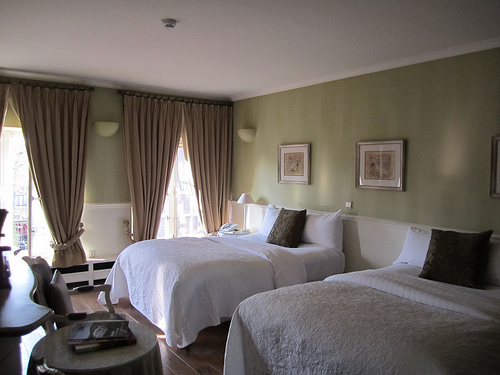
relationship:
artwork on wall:
[354, 137, 407, 194] [230, 46, 500, 239]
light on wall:
[93, 118, 121, 138] [0, 74, 237, 295]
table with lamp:
[205, 229, 252, 240] [238, 191, 255, 232]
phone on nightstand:
[219, 221, 238, 233] [215, 228, 255, 238]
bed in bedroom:
[221, 226, 499, 374] [2, 1, 498, 374]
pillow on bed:
[266, 205, 307, 248] [99, 233, 348, 351]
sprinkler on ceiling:
[162, 18, 178, 29] [2, 2, 500, 103]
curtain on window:
[1, 83, 94, 269] [3, 126, 31, 254]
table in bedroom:
[25, 317, 164, 374] [2, 1, 498, 374]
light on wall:
[236, 126, 258, 145] [230, 46, 500, 239]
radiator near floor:
[49, 257, 116, 293] [1, 284, 232, 374]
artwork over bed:
[355, 138, 407, 191] [99, 233, 348, 351]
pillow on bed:
[419, 227, 494, 292] [221, 226, 499, 374]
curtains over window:
[122, 92, 234, 245] [156, 136, 205, 241]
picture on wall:
[275, 143, 312, 187] [230, 46, 500, 239]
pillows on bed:
[261, 204, 345, 250] [99, 233, 348, 351]